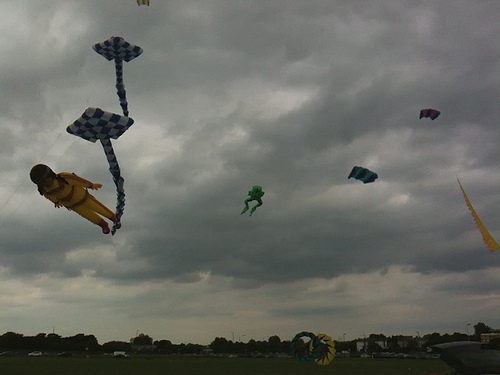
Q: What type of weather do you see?
A: It is cloudy.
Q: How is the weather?
A: It is cloudy.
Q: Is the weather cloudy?
A: Yes, it is cloudy.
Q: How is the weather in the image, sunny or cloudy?
A: It is cloudy.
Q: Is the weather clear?
A: No, it is cloudy.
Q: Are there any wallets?
A: No, there are no wallets.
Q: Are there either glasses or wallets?
A: No, there are no wallets or glasses.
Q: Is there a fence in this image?
A: No, there are no fences.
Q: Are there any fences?
A: No, there are no fences.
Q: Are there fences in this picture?
A: No, there are no fences.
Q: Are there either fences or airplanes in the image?
A: No, there are no fences or airplanes.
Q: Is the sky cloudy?
A: Yes, the sky is cloudy.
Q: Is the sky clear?
A: No, the sky is cloudy.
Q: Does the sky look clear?
A: No, the sky is cloudy.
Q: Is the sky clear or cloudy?
A: The sky is cloudy.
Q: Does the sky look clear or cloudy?
A: The sky is cloudy.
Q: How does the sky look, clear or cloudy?
A: The sky is cloudy.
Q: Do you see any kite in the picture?
A: Yes, there is a kite.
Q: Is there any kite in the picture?
A: Yes, there is a kite.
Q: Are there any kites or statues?
A: Yes, there is a kite.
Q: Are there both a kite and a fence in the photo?
A: No, there is a kite but no fences.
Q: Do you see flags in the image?
A: No, there are no flags.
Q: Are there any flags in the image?
A: No, there are no flags.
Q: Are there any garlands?
A: No, there are no garlands.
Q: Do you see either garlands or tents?
A: No, there are no garlands or tents.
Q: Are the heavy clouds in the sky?
A: Yes, the clouds are in the sky.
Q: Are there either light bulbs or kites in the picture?
A: Yes, there is a kite.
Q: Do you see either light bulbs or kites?
A: Yes, there is a kite.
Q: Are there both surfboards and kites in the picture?
A: No, there is a kite but no surfboards.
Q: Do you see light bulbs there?
A: No, there are no light bulbs.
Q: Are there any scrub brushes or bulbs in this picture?
A: No, there are no bulbs or scrub brushes.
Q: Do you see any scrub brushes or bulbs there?
A: No, there are no bulbs or scrub brushes.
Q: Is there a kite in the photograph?
A: Yes, there is a kite.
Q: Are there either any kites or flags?
A: Yes, there is a kite.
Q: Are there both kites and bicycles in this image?
A: No, there is a kite but no bikes.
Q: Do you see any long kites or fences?
A: Yes, there is a long kite.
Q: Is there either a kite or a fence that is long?
A: Yes, the kite is long.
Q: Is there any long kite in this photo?
A: Yes, there is a long kite.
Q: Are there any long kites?
A: Yes, there is a long kite.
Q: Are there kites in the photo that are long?
A: Yes, there is a long kite.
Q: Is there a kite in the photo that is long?
A: Yes, there is a kite that is long.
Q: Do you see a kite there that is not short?
A: Yes, there is a long kite.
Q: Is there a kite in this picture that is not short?
A: Yes, there is a long kite.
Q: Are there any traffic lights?
A: No, there are no traffic lights.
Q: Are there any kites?
A: Yes, there is a kite.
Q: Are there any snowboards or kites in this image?
A: Yes, there is a kite.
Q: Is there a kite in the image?
A: Yes, there is a kite.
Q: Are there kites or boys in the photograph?
A: Yes, there is a kite.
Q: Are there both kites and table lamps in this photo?
A: No, there is a kite but no table lamps.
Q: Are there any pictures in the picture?
A: No, there are no pictures.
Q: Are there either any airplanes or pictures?
A: No, there are no pictures or airplanes.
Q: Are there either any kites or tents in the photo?
A: Yes, there is a kite.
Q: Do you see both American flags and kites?
A: No, there is a kite but no American flags.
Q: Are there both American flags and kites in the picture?
A: No, there is a kite but no American flags.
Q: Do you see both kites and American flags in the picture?
A: No, there is a kite but no American flags.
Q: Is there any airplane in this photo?
A: No, there are no airplanes.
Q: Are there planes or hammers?
A: No, there are no planes or hammers.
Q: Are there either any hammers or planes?
A: No, there are no planes or hammers.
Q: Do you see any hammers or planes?
A: No, there are no planes or hammers.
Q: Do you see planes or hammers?
A: No, there are no planes or hammers.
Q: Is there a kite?
A: Yes, there is a kite.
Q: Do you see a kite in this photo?
A: Yes, there is a kite.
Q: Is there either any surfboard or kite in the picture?
A: Yes, there is a kite.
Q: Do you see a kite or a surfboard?
A: Yes, there is a kite.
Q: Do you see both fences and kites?
A: No, there is a kite but no fences.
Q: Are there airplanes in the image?
A: No, there are no airplanes.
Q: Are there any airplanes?
A: No, there are no airplanes.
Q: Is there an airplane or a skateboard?
A: No, there are no airplanes or skateboards.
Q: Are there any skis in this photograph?
A: No, there are no skis.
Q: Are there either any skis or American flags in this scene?
A: No, there are no skis or American flags.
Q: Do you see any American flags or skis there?
A: No, there are no skis or American flags.